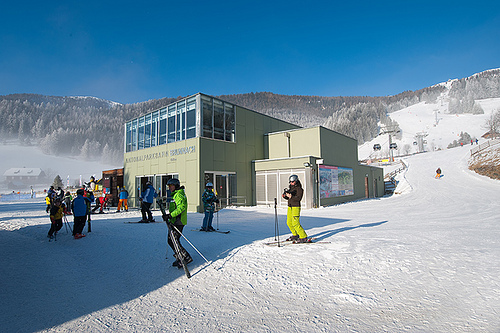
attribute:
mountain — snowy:
[1, 67, 500, 211]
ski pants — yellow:
[284, 204, 309, 238]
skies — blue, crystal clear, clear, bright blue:
[0, 4, 495, 100]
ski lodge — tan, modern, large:
[93, 92, 384, 201]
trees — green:
[6, 67, 497, 156]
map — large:
[318, 164, 357, 200]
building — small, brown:
[4, 167, 48, 188]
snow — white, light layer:
[10, 102, 496, 330]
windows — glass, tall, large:
[124, 91, 236, 155]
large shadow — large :
[2, 201, 341, 332]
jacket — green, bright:
[164, 179, 189, 231]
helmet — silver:
[285, 172, 301, 185]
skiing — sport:
[44, 166, 327, 276]